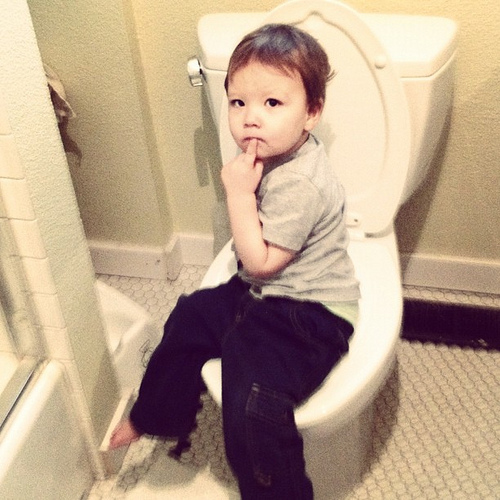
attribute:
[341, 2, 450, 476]
toilet — porcelain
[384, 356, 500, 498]
floor — tiled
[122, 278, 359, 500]
pants — black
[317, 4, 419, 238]
lid — lifted up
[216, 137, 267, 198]
hand — pale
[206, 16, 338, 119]
hair — short brown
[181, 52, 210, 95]
handle — metal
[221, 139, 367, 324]
shirt — gray